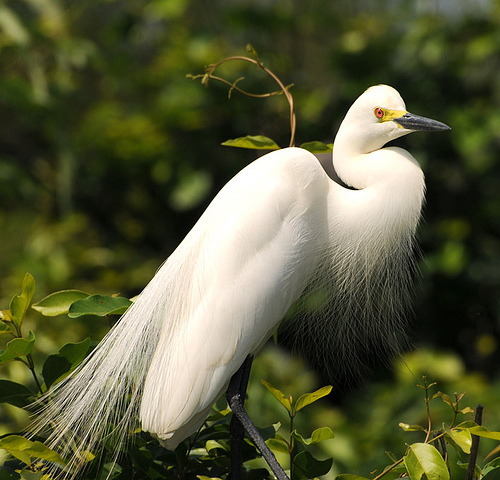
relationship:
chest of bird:
[263, 178, 335, 307] [23, 82, 450, 480]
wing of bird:
[140, 229, 252, 441] [23, 82, 450, 480]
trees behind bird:
[1, 1, 498, 479] [23, 82, 450, 480]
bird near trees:
[23, 82, 450, 480] [1, 1, 498, 479]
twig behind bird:
[189, 44, 295, 146] [23, 82, 450, 480]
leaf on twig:
[223, 133, 279, 151] [189, 44, 295, 146]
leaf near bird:
[32, 289, 88, 315] [23, 82, 450, 480]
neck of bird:
[278, 140, 421, 392] [23, 82, 450, 480]